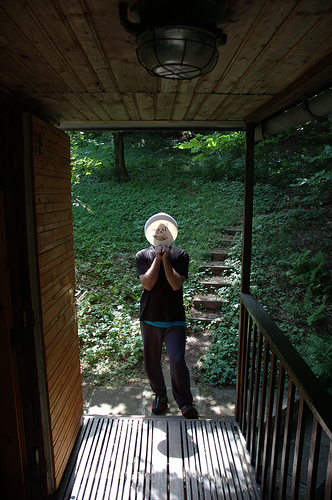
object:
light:
[118, 6, 227, 77]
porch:
[3, 0, 331, 499]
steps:
[186, 304, 220, 334]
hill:
[72, 182, 330, 420]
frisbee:
[143, 213, 181, 251]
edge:
[70, 124, 243, 421]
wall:
[26, 109, 84, 494]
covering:
[69, 132, 330, 386]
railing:
[234, 291, 331, 499]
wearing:
[148, 402, 159, 417]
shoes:
[149, 399, 166, 418]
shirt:
[134, 246, 189, 323]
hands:
[162, 250, 173, 260]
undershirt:
[142, 319, 189, 330]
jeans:
[142, 323, 195, 407]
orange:
[148, 400, 154, 415]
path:
[190, 185, 251, 333]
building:
[6, 4, 327, 499]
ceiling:
[2, 2, 331, 129]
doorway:
[5, 86, 242, 500]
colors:
[149, 218, 173, 245]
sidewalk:
[85, 385, 307, 421]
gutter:
[249, 85, 331, 143]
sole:
[183, 410, 196, 420]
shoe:
[177, 402, 199, 418]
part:
[168, 361, 186, 379]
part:
[279, 422, 309, 462]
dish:
[283, 439, 320, 476]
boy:
[134, 211, 198, 419]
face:
[152, 223, 172, 245]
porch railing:
[238, 308, 321, 497]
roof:
[29, 26, 321, 140]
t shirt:
[134, 242, 188, 327]